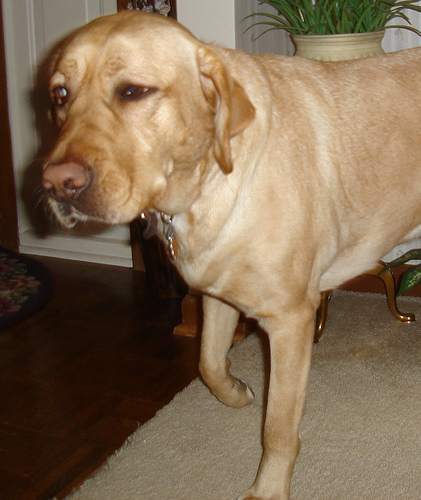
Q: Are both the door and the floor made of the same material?
A: Yes, both the door and the floor are made of wood.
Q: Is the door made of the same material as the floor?
A: Yes, both the door and the floor are made of wood.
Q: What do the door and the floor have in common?
A: The material, both the door and the floor are wooden.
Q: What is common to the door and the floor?
A: The material, both the door and the floor are wooden.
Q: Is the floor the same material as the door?
A: Yes, both the floor and the door are made of wood.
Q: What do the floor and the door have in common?
A: The material, both the floor and the door are wooden.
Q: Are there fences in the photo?
A: No, there are no fences.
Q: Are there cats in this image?
A: No, there are no cats.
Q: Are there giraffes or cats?
A: No, there are no cats or giraffes.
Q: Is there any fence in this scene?
A: No, there are no fences.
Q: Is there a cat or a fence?
A: No, there are no fences or cats.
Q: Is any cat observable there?
A: No, there are no cats.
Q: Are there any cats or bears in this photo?
A: No, there are no cats or bears.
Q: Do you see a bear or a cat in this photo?
A: No, there are no cats or bears.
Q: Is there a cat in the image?
A: No, there are no cats.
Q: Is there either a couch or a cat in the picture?
A: No, there are no cats or couches.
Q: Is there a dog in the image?
A: Yes, there is a dog.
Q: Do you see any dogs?
A: Yes, there is a dog.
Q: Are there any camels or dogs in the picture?
A: Yes, there is a dog.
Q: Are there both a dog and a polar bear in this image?
A: No, there is a dog but no polar bears.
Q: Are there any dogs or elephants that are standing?
A: Yes, the dog is standing.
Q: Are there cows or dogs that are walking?
A: Yes, the dog is walking.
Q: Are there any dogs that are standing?
A: Yes, there is a dog that is standing.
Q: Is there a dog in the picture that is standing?
A: Yes, there is a dog that is standing.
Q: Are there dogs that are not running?
A: Yes, there is a dog that is standing.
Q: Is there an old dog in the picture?
A: Yes, there is an old dog.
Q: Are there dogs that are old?
A: Yes, there is a dog that is old.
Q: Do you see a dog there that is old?
A: Yes, there is a dog that is old.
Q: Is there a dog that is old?
A: Yes, there is a dog that is old.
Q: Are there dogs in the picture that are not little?
A: Yes, there is a old dog.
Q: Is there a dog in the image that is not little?
A: Yes, there is a old dog.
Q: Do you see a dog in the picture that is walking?
A: Yes, there is a dog that is walking.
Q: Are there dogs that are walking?
A: Yes, there is a dog that is walking.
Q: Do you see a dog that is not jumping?
A: Yes, there is a dog that is walking .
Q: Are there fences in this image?
A: No, there are no fences.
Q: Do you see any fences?
A: No, there are no fences.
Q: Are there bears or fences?
A: No, there are no fences or bears.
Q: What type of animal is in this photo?
A: The animal is a dog.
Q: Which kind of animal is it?
A: The animal is a dog.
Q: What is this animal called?
A: That is a dog.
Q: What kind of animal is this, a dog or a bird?
A: That is a dog.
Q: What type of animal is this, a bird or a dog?
A: That is a dog.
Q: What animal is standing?
A: The animal is a dog.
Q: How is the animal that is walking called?
A: The animal is a dog.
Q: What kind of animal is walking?
A: The animal is a dog.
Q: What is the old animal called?
A: The animal is a dog.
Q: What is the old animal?
A: The animal is a dog.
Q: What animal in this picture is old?
A: The animal is a dog.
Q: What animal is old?
A: The animal is a dog.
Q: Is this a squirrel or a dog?
A: This is a dog.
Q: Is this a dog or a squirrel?
A: This is a dog.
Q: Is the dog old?
A: Yes, the dog is old.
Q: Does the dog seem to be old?
A: Yes, the dog is old.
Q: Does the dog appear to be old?
A: Yes, the dog is old.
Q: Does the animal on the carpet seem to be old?
A: Yes, the dog is old.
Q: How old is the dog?
A: The dog is old.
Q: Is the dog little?
A: No, the dog is old.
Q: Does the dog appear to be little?
A: No, the dog is old.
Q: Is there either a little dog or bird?
A: No, there is a dog but it is old.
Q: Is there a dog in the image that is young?
A: No, there is a dog but it is old.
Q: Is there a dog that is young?
A: No, there is a dog but it is old.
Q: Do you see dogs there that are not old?
A: No, there is a dog but it is old.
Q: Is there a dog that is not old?
A: No, there is a dog but it is old.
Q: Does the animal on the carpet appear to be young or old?
A: The dog is old.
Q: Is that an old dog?
A: Yes, that is an old dog.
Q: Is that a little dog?
A: No, that is an old dog.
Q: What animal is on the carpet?
A: The dog is on the carpet.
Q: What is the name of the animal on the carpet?
A: The animal is a dog.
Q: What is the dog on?
A: The dog is on the carpet.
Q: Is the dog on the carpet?
A: Yes, the dog is on the carpet.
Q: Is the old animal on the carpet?
A: Yes, the dog is on the carpet.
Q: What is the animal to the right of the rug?
A: The animal is a dog.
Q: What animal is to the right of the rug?
A: The animal is a dog.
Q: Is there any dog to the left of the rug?
A: No, the dog is to the right of the rug.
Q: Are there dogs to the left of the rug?
A: No, the dog is to the right of the rug.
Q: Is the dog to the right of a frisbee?
A: No, the dog is to the right of the rug.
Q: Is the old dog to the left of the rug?
A: No, the dog is to the right of the rug.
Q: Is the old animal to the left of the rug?
A: No, the dog is to the right of the rug.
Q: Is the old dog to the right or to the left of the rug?
A: The dog is to the right of the rug.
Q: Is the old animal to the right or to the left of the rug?
A: The dog is to the right of the rug.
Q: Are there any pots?
A: Yes, there is a pot.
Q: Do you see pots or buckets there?
A: Yes, there is a pot.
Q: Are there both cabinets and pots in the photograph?
A: No, there is a pot but no cabinets.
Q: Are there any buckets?
A: No, there are no buckets.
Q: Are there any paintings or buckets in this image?
A: No, there are no buckets or paintings.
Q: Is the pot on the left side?
A: No, the pot is on the right of the image.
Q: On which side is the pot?
A: The pot is on the right of the image.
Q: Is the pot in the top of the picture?
A: Yes, the pot is in the top of the image.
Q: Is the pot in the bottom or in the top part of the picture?
A: The pot is in the top of the image.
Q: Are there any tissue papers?
A: No, there are no tissue papers.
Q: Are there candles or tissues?
A: No, there are no tissues or candles.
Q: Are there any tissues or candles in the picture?
A: No, there are no tissues or candles.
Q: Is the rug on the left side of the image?
A: Yes, the rug is on the left of the image.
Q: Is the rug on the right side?
A: No, the rug is on the left of the image.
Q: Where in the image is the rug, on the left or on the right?
A: The rug is on the left of the image.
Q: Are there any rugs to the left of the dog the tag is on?
A: Yes, there is a rug to the left of the dog.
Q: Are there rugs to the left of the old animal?
A: Yes, there is a rug to the left of the dog.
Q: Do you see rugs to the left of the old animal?
A: Yes, there is a rug to the left of the dog.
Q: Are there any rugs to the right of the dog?
A: No, the rug is to the left of the dog.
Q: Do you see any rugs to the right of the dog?
A: No, the rug is to the left of the dog.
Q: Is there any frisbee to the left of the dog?
A: No, there is a rug to the left of the dog.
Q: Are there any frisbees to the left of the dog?
A: No, there is a rug to the left of the dog.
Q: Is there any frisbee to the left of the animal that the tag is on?
A: No, there is a rug to the left of the dog.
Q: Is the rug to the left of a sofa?
A: No, the rug is to the left of the dog.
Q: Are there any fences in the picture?
A: No, there are no fences.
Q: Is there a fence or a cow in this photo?
A: No, there are no fences or cows.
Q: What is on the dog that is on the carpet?
A: The tag is on the dog.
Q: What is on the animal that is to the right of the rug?
A: The tag is on the dog.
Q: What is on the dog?
A: The tag is on the dog.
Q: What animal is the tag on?
A: The tag is on the dog.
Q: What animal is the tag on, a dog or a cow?
A: The tag is on a dog.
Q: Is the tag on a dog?
A: Yes, the tag is on a dog.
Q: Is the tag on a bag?
A: No, the tag is on a dog.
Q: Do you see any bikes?
A: No, there are no bikes.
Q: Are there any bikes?
A: No, there are no bikes.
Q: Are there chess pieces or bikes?
A: No, there are no bikes or chess pieces.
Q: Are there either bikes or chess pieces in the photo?
A: No, there are no bikes or chess pieces.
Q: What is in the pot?
A: The plant is in the pot.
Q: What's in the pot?
A: The plant is in the pot.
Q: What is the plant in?
A: The plant is in the pot.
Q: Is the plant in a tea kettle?
A: No, the plant is in the pot.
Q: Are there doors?
A: Yes, there is a door.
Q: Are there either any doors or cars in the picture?
A: Yes, there is a door.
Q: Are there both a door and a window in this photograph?
A: No, there is a door but no windows.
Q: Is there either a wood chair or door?
A: Yes, there is a wood door.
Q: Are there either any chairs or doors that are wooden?
A: Yes, the door is wooden.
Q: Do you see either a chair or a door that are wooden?
A: Yes, the door is wooden.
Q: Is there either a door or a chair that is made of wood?
A: Yes, the door is made of wood.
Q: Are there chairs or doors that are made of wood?
A: Yes, the door is made of wood.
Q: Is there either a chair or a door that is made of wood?
A: Yes, the door is made of wood.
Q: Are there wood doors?
A: Yes, there is a door that is made of wood.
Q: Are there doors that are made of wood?
A: Yes, there is a door that is made of wood.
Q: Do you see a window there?
A: No, there are no windows.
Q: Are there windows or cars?
A: No, there are no windows or cars.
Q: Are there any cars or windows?
A: No, there are no windows or cars.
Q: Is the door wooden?
A: Yes, the door is wooden.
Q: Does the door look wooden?
A: Yes, the door is wooden.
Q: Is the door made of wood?
A: Yes, the door is made of wood.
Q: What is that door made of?
A: The door is made of wood.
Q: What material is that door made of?
A: The door is made of wood.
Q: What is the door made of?
A: The door is made of wood.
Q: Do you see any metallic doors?
A: No, there is a door but it is wooden.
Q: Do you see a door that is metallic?
A: No, there is a door but it is wooden.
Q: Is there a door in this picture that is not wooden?
A: No, there is a door but it is wooden.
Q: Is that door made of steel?
A: No, the door is made of wood.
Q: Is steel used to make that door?
A: No, the door is made of wood.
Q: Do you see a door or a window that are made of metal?
A: No, there is a door but it is made of wood.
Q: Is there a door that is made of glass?
A: No, there is a door but it is made of wood.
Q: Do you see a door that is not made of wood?
A: No, there is a door but it is made of wood.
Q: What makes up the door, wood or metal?
A: The door is made of wood.